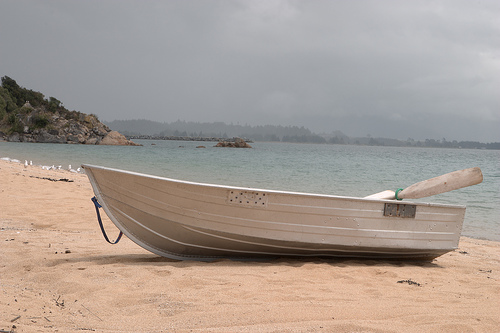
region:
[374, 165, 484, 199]
a white oar sticking out of a boat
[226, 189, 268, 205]
holes in a grid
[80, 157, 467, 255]
a white boat on the shore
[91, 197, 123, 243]
a tether hanging down from the boat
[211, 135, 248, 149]
a rock protruding from the ocean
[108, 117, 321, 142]
a group of trees in the distance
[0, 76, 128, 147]
a large tree covered rocky hill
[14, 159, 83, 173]
white birds along the shoreline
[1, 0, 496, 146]
a gray cloudy sky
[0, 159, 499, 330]
a light brown sandy beach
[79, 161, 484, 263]
Boat sitting on the beach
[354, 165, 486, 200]
Oar sticking out of the boat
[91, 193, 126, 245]
Rope tied to the front of the boat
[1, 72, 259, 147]
Rocks jutting out into the water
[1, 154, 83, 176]
Seagulls on the beach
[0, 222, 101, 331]
Sticks and stuff in the sand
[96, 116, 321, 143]
Tall trees in the background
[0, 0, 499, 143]
Mostly cloudy skies above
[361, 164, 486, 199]
The oar is made from wood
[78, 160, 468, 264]
The boat is made from aluminum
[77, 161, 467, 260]
silver metal boat on sandy beach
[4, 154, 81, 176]
white bird on beach by waters edge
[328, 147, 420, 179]
rough blue water on ocean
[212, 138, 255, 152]
brown rocks out in ocean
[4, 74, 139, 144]
rocky hillside by waters edge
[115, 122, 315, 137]
tree line in the distance by ocean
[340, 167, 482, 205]
white oars in silver metal brown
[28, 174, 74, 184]
seaweed on sandy beach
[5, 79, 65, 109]
green trees on rocky hillside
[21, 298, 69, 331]
small sticks on sandy beach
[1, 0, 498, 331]
This is a beach scene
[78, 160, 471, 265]
A boat is on the beach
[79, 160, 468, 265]
The boat is silver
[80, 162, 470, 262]
The boat is made of aluminum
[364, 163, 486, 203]
An oar is in the boat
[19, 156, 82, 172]
Seagulls are on the beach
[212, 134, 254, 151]
A small island is in the water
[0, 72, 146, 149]
An outcropping of land extends into the water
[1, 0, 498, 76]
The sky is cloudy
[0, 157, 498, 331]
The beach is made of sand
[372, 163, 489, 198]
a battered wooden oar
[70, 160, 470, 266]
a white aluminum canoe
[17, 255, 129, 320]
beach sand with debris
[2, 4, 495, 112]
grey and stormy sky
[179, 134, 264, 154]
small rocky outcropping in the water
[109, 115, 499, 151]
mountains in the distance through haze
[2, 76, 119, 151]
brush covered rocky outcropping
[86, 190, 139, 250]
blue tether on aluminum canoe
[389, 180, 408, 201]
green ring on battered wooden oar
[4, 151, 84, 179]
flock of seagulls on the beach